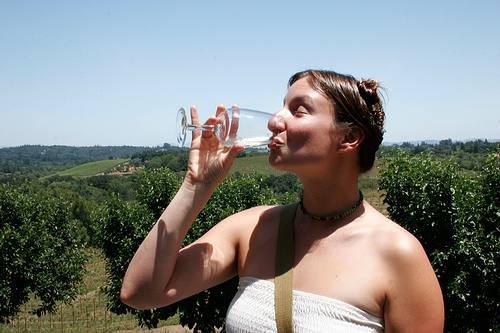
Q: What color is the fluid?
A: Clear.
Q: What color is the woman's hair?
A: Brown.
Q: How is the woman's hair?
A: Pinned up.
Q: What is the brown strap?
A: Purse.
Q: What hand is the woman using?
A: Right.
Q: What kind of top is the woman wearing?
A: Tube.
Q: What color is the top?
A: White.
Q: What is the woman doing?
A: Drinking wine.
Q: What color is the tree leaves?
A: Dark green.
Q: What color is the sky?
A: Blue sky.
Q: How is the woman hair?
A: Pulled back.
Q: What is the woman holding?
A: Wine glass.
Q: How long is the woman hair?
A: Short.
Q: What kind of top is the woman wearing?
A: Strapless.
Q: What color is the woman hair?
A: Brown.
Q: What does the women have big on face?
A: Nose.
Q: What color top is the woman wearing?
A: White.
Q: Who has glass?
A: Woman in vineyard.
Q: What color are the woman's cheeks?
A: Rosy.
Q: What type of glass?
A: Clear glass.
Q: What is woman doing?
A: Drinking.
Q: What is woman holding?
A: Wine glass.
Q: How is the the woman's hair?
A: It is up.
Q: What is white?
A: Strapless top.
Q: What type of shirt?
A: Strapless.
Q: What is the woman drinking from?
A: Glass.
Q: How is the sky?
A: Clear with no clouds.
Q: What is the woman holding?
A: Glass.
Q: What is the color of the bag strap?
A: Brown.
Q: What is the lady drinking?
A: Water.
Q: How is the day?
A: Sunny.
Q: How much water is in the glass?
A: Little water.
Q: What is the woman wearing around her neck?
A: A necklace.